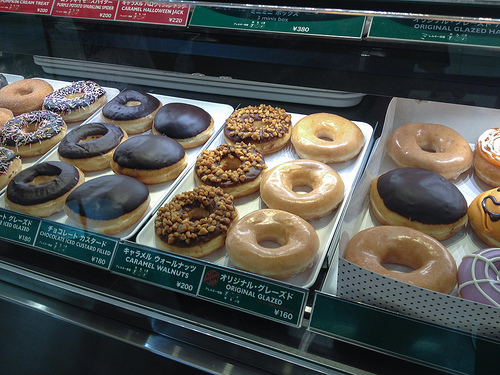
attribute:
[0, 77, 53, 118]
donut — plain, cake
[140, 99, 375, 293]
tray — white, long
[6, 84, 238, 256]
tray — white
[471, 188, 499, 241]
frosting — orange, black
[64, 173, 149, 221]
frosting — chocolate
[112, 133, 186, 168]
frosting — chocolate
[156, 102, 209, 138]
frosting — chocolate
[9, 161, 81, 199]
frosting — chocolate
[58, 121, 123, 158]
frosting — chocolate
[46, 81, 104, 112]
frosting — chocolate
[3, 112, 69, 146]
frosting — chocolate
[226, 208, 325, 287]
doughnut — glazed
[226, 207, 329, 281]
glaze — plain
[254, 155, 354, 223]
doughnut — glazed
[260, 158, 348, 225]
glaze — plain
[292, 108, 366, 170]
doughnut — glazed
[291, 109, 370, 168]
glaze — plain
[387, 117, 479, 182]
doughnut — glazed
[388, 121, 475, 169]
glaze — plain, original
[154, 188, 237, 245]
frosting — chocolate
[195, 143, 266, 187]
frosting — chocolate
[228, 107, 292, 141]
frosting — chocolate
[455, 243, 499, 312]
doughnut — pink, white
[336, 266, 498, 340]
design — krispy kreme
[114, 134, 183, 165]
icing — chocolate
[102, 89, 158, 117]
glaze — chocolate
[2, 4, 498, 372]
case — silver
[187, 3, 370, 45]
placard — green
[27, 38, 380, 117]
tray — silver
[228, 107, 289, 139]
icing — chocolate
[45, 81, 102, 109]
icing — chocolate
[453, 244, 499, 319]
frosting — purple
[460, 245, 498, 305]
design — white, icing